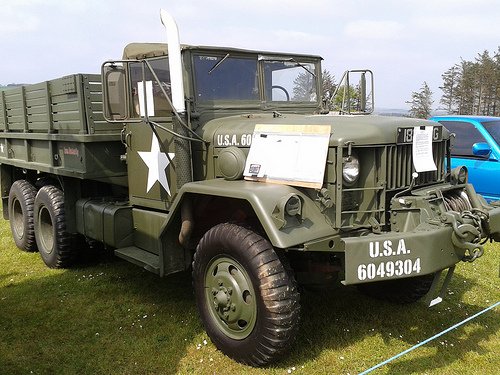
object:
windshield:
[193, 55, 318, 101]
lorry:
[0, 7, 499, 368]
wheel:
[190, 223, 305, 368]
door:
[120, 55, 178, 211]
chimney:
[158, 8, 194, 188]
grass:
[4, 285, 134, 355]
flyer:
[242, 124, 331, 190]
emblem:
[136, 132, 176, 197]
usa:
[217, 134, 239, 146]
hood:
[197, 111, 456, 149]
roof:
[122, 42, 324, 59]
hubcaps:
[203, 257, 258, 340]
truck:
[429, 115, 500, 204]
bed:
[0, 72, 104, 142]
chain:
[440, 208, 489, 263]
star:
[136, 132, 175, 197]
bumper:
[340, 227, 465, 285]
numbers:
[357, 257, 421, 281]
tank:
[75, 196, 134, 248]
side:
[0, 74, 213, 199]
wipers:
[207, 54, 229, 74]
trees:
[455, 63, 492, 110]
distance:
[330, 69, 380, 116]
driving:
[241, 55, 319, 116]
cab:
[100, 42, 329, 124]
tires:
[33, 184, 78, 268]